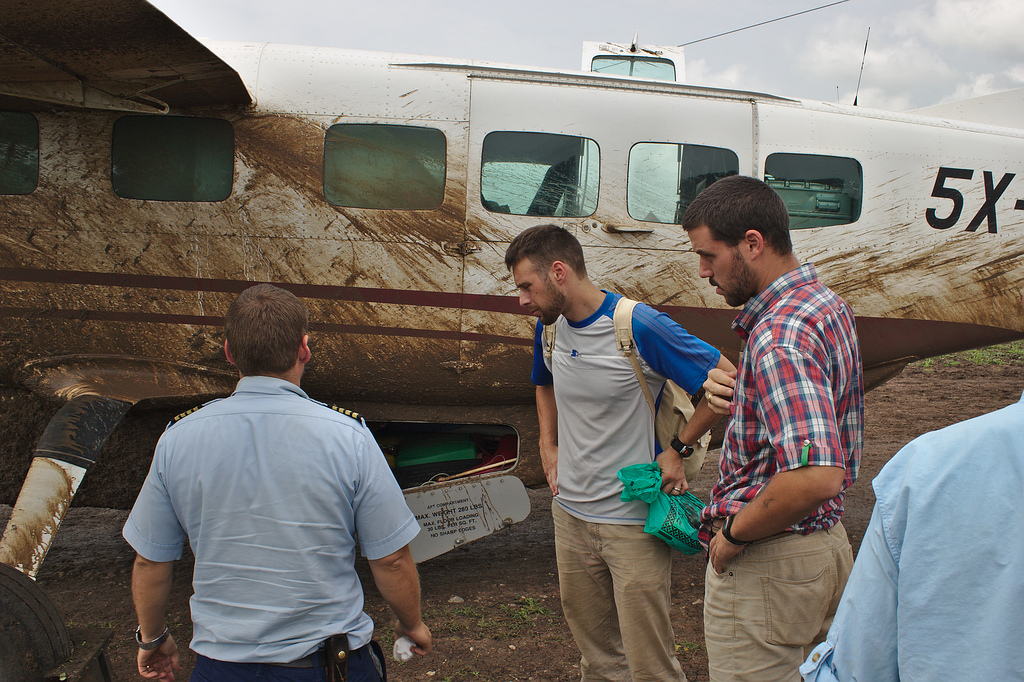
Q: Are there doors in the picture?
A: Yes, there is a door.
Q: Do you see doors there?
A: Yes, there is a door.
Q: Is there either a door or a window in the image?
A: Yes, there is a door.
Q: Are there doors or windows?
A: Yes, there is a door.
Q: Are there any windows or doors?
A: Yes, there is a door.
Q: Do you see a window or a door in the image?
A: Yes, there is a door.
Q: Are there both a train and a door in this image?
A: No, there is a door but no trains.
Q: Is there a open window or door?
A: Yes, there is an open door.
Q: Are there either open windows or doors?
A: Yes, there is an open door.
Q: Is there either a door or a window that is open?
A: Yes, the door is open.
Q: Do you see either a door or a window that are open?
A: Yes, the door is open.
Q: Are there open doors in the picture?
A: Yes, there is an open door.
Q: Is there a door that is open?
A: Yes, there is a door that is open.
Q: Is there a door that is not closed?
A: Yes, there is a open door.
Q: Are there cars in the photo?
A: No, there are no cars.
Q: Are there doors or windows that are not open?
A: No, there is a door but it is open.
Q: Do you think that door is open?
A: Yes, the door is open.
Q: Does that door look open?
A: Yes, the door is open.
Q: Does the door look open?
A: Yes, the door is open.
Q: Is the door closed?
A: No, the door is open.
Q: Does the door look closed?
A: No, the door is open.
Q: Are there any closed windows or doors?
A: No, there is a door but it is open.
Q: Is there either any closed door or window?
A: No, there is a door but it is open.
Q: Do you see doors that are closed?
A: No, there is a door but it is open.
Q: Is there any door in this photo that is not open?
A: No, there is a door but it is open.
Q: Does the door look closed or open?
A: The door is open.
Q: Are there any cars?
A: No, there are no cars.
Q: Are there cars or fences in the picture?
A: No, there are no cars or fences.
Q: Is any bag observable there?
A: Yes, there is a bag.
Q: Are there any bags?
A: Yes, there is a bag.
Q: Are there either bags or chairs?
A: Yes, there is a bag.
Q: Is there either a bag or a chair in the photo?
A: Yes, there is a bag.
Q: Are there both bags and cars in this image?
A: No, there is a bag but no cars.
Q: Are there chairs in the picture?
A: No, there are no chairs.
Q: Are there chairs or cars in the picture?
A: No, there are no chairs or cars.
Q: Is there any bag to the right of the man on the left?
A: Yes, there is a bag to the right of the man.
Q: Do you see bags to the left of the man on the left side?
A: No, the bag is to the right of the man.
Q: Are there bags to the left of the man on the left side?
A: No, the bag is to the right of the man.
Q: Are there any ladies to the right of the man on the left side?
A: No, there is a bag to the right of the man.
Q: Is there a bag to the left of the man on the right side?
A: Yes, there is a bag to the left of the man.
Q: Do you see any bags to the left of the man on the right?
A: Yes, there is a bag to the left of the man.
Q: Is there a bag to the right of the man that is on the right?
A: No, the bag is to the left of the man.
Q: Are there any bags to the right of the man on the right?
A: No, the bag is to the left of the man.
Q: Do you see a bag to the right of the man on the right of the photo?
A: No, the bag is to the left of the man.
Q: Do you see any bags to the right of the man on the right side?
A: No, the bag is to the left of the man.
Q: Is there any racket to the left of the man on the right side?
A: No, there is a bag to the left of the man.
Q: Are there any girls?
A: No, there are no girls.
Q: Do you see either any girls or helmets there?
A: No, there are no girls or helmets.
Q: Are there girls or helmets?
A: No, there are no girls or helmets.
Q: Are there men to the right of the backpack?
A: Yes, there is a man to the right of the backpack.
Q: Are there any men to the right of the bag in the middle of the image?
A: Yes, there is a man to the right of the backpack.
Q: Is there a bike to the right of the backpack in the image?
A: No, there is a man to the right of the backpack.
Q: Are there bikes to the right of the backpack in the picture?
A: No, there is a man to the right of the backpack.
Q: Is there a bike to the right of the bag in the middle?
A: No, there is a man to the right of the backpack.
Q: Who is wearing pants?
A: The man is wearing pants.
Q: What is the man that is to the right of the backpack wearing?
A: The man is wearing trousers.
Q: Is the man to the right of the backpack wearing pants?
A: Yes, the man is wearing pants.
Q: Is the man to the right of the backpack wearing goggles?
A: No, the man is wearing pants.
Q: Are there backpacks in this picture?
A: Yes, there is a backpack.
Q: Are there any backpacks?
A: Yes, there is a backpack.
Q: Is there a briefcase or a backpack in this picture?
A: Yes, there is a backpack.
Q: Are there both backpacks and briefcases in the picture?
A: No, there is a backpack but no briefcases.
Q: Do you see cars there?
A: No, there are no cars.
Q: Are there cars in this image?
A: No, there are no cars.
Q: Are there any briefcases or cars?
A: No, there are no cars or briefcases.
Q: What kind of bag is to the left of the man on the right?
A: The bag is a backpack.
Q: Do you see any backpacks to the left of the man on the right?
A: Yes, there is a backpack to the left of the man.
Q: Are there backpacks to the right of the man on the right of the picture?
A: No, the backpack is to the left of the man.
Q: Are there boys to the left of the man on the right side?
A: No, there is a backpack to the left of the man.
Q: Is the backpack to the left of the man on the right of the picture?
A: Yes, the backpack is to the left of the man.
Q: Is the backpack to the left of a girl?
A: No, the backpack is to the left of the man.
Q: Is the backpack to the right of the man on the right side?
A: No, the backpack is to the left of the man.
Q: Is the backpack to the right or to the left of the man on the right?
A: The backpack is to the left of the man.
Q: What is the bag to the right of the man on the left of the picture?
A: The bag is a backpack.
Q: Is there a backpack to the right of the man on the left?
A: Yes, there is a backpack to the right of the man.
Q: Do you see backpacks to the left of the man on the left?
A: No, the backpack is to the right of the man.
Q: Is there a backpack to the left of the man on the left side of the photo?
A: No, the backpack is to the right of the man.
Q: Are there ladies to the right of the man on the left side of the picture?
A: No, there is a backpack to the right of the man.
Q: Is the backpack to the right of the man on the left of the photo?
A: Yes, the backpack is to the right of the man.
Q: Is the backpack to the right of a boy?
A: No, the backpack is to the right of the man.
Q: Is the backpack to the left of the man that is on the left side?
A: No, the backpack is to the right of the man.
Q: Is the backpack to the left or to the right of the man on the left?
A: The backpack is to the right of the man.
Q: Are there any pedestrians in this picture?
A: No, there are no pedestrians.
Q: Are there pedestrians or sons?
A: No, there are no pedestrians or sons.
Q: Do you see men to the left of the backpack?
A: Yes, there is a man to the left of the backpack.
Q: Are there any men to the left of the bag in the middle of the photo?
A: Yes, there is a man to the left of the backpack.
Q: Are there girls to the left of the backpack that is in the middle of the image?
A: No, there is a man to the left of the backpack.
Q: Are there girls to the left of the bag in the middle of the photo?
A: No, there is a man to the left of the backpack.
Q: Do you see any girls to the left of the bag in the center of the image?
A: No, there is a man to the left of the backpack.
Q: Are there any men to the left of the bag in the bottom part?
A: Yes, there is a man to the left of the bag.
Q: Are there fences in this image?
A: No, there are no fences.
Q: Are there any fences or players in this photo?
A: No, there are no fences or players.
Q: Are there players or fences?
A: No, there are no fences or players.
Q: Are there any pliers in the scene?
A: No, there are no pliers.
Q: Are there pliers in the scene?
A: No, there are no pliers.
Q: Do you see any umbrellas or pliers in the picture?
A: No, there are no pliers or umbrellas.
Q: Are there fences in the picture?
A: No, there are no fences.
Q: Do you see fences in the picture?
A: No, there are no fences.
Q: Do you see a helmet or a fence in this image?
A: No, there are no fences or helmets.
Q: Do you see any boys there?
A: No, there are no boys.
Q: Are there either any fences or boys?
A: No, there are no boys or fences.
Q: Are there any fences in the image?
A: No, there are no fences.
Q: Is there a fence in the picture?
A: No, there are no fences.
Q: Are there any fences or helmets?
A: No, there are no fences or helmets.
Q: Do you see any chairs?
A: No, there are no chairs.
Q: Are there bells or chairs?
A: No, there are no chairs or bells.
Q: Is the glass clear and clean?
A: Yes, the glass is clear and clean.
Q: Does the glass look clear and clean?
A: Yes, the glass is clear and clean.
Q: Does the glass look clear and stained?
A: No, the glass is clear but clean.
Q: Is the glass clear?
A: Yes, the glass is clear.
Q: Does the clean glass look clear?
A: Yes, the glass is clear.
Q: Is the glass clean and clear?
A: Yes, the glass is clean and clear.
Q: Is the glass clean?
A: Yes, the glass is clean.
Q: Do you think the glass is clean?
A: Yes, the glass is clean.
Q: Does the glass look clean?
A: Yes, the glass is clean.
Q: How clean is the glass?
A: The glass is clean.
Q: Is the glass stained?
A: No, the glass is clean.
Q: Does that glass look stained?
A: No, the glass is clean.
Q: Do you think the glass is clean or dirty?
A: The glass is clean.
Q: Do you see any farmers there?
A: No, there are no farmers.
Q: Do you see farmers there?
A: No, there are no farmers.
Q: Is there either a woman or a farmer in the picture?
A: No, there are no farmers or women.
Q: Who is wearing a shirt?
A: The man is wearing a shirt.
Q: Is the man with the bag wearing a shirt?
A: Yes, the man is wearing a shirt.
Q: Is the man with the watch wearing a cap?
A: No, the man is wearing a shirt.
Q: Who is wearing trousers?
A: The man is wearing trousers.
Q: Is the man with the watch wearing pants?
A: Yes, the man is wearing pants.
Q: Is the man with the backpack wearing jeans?
A: No, the man is wearing pants.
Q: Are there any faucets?
A: No, there are no faucets.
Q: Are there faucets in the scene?
A: No, there are no faucets.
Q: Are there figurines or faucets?
A: No, there are no faucets or figurines.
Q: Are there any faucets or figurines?
A: No, there are no faucets or figurines.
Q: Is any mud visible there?
A: Yes, there is mud.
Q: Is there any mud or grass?
A: Yes, there is mud.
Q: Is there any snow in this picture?
A: No, there is no snow.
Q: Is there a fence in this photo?
A: No, there are no fences.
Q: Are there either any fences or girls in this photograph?
A: No, there are no fences or girls.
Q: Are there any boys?
A: No, there are no boys.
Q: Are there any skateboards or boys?
A: No, there are no boys or skateboards.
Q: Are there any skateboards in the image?
A: No, there are no skateboards.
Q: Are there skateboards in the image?
A: No, there are no skateboards.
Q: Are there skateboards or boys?
A: No, there are no skateboards or boys.